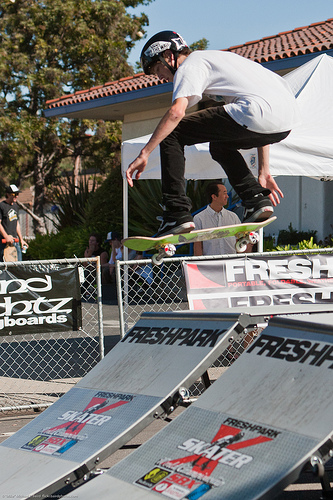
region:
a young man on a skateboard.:
[106, 21, 302, 260]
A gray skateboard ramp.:
[0, 297, 268, 498]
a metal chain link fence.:
[105, 240, 331, 346]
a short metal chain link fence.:
[0, 247, 117, 432]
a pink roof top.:
[40, 15, 332, 123]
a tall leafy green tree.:
[0, 0, 152, 252]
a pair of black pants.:
[153, 115, 289, 203]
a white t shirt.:
[166, 28, 316, 132]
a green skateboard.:
[126, 197, 294, 281]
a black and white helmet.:
[131, 23, 201, 76]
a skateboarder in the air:
[119, 30, 295, 264]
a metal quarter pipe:
[60, 315, 328, 497]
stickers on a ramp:
[22, 433, 77, 458]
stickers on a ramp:
[133, 464, 209, 496]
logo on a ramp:
[161, 418, 275, 489]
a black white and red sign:
[180, 258, 331, 307]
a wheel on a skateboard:
[164, 244, 175, 255]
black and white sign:
[0, 267, 81, 333]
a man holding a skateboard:
[1, 187, 28, 260]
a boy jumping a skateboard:
[92, 27, 314, 301]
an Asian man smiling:
[178, 174, 263, 268]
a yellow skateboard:
[115, 217, 290, 277]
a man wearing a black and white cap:
[0, 179, 29, 267]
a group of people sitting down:
[61, 223, 160, 296]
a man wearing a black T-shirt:
[0, 182, 33, 266]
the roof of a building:
[26, 18, 331, 129]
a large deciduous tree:
[1, 1, 124, 242]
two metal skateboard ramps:
[1, 302, 328, 498]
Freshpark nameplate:
[122, 321, 229, 358]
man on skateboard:
[131, 52, 301, 244]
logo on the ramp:
[162, 435, 249, 473]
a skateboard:
[122, 225, 272, 265]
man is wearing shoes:
[156, 220, 204, 234]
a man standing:
[195, 181, 236, 223]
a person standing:
[1, 185, 28, 264]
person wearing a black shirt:
[4, 206, 22, 236]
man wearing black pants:
[161, 141, 187, 197]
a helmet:
[135, 33, 183, 56]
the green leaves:
[276, 237, 321, 249]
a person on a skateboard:
[87, 21, 304, 270]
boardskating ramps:
[41, 313, 332, 457]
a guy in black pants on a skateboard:
[101, 14, 289, 254]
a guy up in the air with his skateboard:
[86, 21, 306, 315]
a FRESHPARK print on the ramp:
[120, 322, 225, 355]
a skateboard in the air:
[116, 212, 282, 263]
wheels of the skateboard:
[148, 243, 181, 265]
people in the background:
[0, 181, 123, 267]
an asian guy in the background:
[198, 177, 231, 214]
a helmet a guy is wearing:
[136, 27, 189, 75]